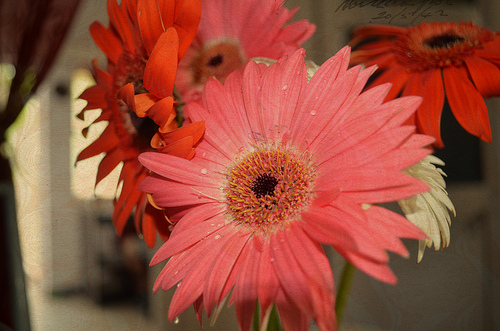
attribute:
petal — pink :
[282, 221, 336, 293]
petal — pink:
[319, 150, 431, 221]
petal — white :
[391, 193, 426, 262]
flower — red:
[349, 19, 494, 134]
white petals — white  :
[405, 156, 457, 263]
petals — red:
[139, 23, 185, 103]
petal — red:
[420, 66, 443, 145]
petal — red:
[435, 57, 482, 139]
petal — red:
[141, 31, 174, 111]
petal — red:
[369, 59, 402, 94]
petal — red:
[200, 222, 245, 309]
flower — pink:
[135, 61, 429, 328]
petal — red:
[416, 64, 443, 147]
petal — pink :
[136, 55, 425, 329]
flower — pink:
[141, 53, 406, 329]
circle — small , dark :
[249, 170, 279, 195]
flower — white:
[140, 57, 470, 318]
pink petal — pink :
[137, 149, 230, 192]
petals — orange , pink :
[163, 116, 203, 151]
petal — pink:
[271, 239, 339, 309]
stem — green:
[330, 262, 350, 329]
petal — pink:
[295, 61, 360, 150]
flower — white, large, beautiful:
[392, 152, 457, 260]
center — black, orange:
[419, 26, 463, 51]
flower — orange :
[347, 17, 498, 149]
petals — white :
[406, 151, 458, 256]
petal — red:
[367, 63, 406, 103]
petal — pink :
[311, 49, 337, 159]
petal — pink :
[270, 61, 298, 150]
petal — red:
[147, 30, 177, 103]